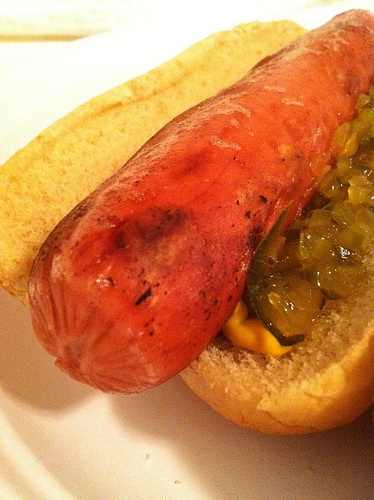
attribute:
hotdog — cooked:
[25, 9, 372, 394]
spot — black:
[115, 204, 209, 288]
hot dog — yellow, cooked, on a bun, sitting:
[24, 4, 373, 398]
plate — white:
[7, 14, 369, 96]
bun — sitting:
[3, 11, 290, 180]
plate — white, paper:
[1, 336, 372, 495]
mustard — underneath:
[220, 295, 293, 357]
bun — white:
[54, 70, 232, 135]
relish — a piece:
[295, 183, 373, 356]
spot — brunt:
[254, 192, 272, 207]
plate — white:
[0, 0, 373, 496]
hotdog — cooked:
[6, 72, 334, 468]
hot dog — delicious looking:
[0, 2, 374, 444]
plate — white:
[16, 376, 260, 498]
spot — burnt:
[126, 279, 160, 313]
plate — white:
[5, 25, 341, 487]